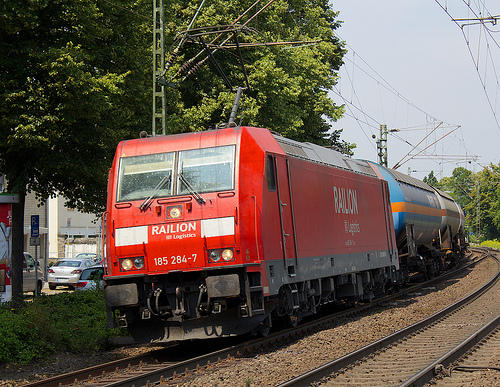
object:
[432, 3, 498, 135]
line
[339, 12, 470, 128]
line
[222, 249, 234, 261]
headlight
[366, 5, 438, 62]
sky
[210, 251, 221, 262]
lights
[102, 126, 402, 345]
engine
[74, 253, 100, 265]
car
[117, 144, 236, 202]
windshield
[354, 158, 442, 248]
tank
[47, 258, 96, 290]
car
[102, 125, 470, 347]
train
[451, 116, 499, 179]
sky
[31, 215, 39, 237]
blue sign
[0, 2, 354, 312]
tree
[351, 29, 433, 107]
sky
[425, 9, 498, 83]
sky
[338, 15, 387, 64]
sky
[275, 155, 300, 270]
steps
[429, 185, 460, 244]
tank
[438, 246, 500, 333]
track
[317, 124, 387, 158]
sky